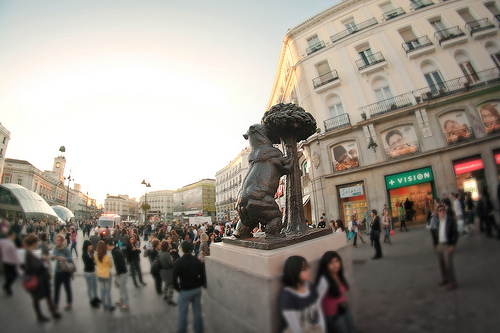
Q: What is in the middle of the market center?
A: A statue.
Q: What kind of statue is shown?
A: An animal and tree.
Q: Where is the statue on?
A: A stone platform.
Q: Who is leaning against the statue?
A: Two young girls.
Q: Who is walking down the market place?
A: A crowd of people.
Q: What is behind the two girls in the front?
A: A statue.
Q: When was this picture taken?
A: During the day.